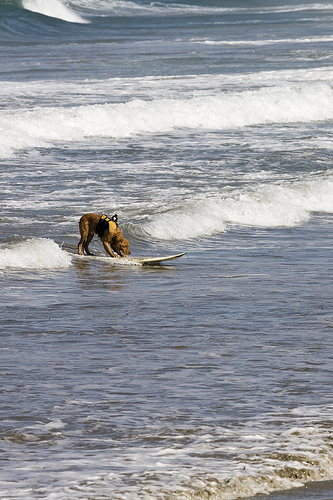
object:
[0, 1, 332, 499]
pond